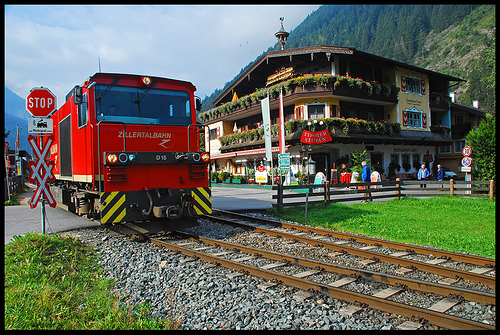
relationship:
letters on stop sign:
[26, 96, 56, 107] [23, 88, 56, 118]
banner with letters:
[295, 128, 336, 145] [300, 132, 328, 145]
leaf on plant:
[372, 13, 397, 34] [271, 5, 477, 58]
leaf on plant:
[409, 23, 415, 32] [275, 0, 473, 59]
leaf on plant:
[321, 12, 330, 25] [283, 4, 475, 47]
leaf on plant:
[391, 22, 401, 34] [288, 0, 476, 61]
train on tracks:
[36, 69, 212, 230] [104, 210, 495, 330]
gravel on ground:
[77, 228, 492, 327] [4, 184, 493, 326]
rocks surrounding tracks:
[242, 315, 254, 325] [131, 227, 500, 334]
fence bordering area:
[268, 174, 484, 209] [346, 198, 485, 241]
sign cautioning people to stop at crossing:
[26, 84, 59, 235] [14, 180, 257, 228]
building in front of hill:
[206, 39, 485, 187] [207, 4, 484, 114]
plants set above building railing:
[209, 74, 378, 108] [204, 83, 398, 116]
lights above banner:
[304, 120, 326, 127] [296, 127, 334, 146]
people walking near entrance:
[300, 155, 448, 193] [302, 146, 332, 182]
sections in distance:
[0, 81, 24, 146] [1, 6, 219, 143]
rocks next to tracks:
[144, 259, 236, 319] [177, 215, 452, 332]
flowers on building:
[224, 113, 400, 143] [203, 16, 483, 186]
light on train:
[104, 149, 119, 164] [36, 69, 212, 230]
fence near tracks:
[268, 174, 484, 209] [186, 215, 484, 317]